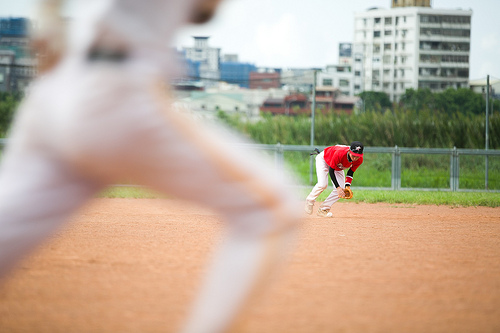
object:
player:
[302, 141, 364, 217]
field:
[0, 195, 499, 332]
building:
[350, 6, 473, 116]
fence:
[0, 137, 500, 193]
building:
[259, 86, 362, 118]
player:
[0, 0, 308, 333]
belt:
[83, 46, 130, 64]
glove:
[338, 189, 353, 199]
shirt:
[324, 144, 364, 172]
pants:
[305, 150, 345, 213]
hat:
[349, 141, 364, 157]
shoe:
[315, 207, 332, 218]